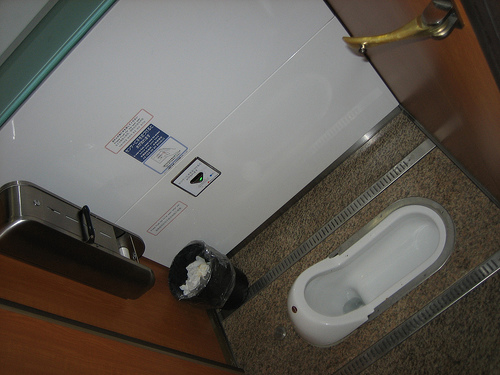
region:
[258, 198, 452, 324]
A foreign floor toilet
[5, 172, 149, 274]
A paper towel dispenser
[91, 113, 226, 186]
Signs hanging on wall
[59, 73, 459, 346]
A scene in a bathroom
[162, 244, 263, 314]
A small trash can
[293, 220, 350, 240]
A small aluminum drain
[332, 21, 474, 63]
A wall mount hook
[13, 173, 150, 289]
Towel dispenser attached at wall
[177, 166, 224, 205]
Special button for disabled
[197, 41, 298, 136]
White brick bathroom wall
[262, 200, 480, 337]
white urinal on floor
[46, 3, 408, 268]
white wall of tile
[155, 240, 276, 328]
trash can on floor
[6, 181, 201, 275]
toilet paper dispenser is silver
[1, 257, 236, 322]
brown walls of bathroom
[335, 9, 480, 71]
gold handle of door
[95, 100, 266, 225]
stickers on white wall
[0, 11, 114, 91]
blue beam on white wall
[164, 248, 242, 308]
plastic bag in trash can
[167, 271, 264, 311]
white garbage in bin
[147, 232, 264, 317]
black trash can in corner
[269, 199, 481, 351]
white urinal on the ground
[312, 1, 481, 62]
handle to a door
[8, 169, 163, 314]
silver toilet paper dispenser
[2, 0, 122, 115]
green ledge on a white wall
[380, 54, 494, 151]
brown wooden door in a bathroom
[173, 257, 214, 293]
white paper trash in can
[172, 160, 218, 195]
green light on the wall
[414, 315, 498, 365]
speckled brown flooring near urinal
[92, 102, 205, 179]
instruction signs on the wall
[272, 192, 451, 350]
a floor squat toilet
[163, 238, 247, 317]
a lined trash can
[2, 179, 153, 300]
a wall mounted toilet paper dispenser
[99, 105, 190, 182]
instructional labels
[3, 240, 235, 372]
dark brown wooden panels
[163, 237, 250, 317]
a trash can filled with paper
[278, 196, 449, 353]
a white porcelain toilet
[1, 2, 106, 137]
a green shelf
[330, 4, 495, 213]
a dark wood panel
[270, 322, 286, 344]
a chrome flush button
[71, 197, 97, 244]
paper towel dispenser lever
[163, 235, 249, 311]
trashcan filled with used paper towels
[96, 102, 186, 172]
two signs posted on white wall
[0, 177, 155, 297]
tissue dispenser posted on brown wall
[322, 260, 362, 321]
water in bottom of floor urinal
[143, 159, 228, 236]
additional signposts on white side wall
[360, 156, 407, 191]
steel track on urinal area floor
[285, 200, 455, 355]
built-in floor white porcelain urinal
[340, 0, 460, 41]
door handle to urinal area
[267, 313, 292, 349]
small floor drain next to urinal